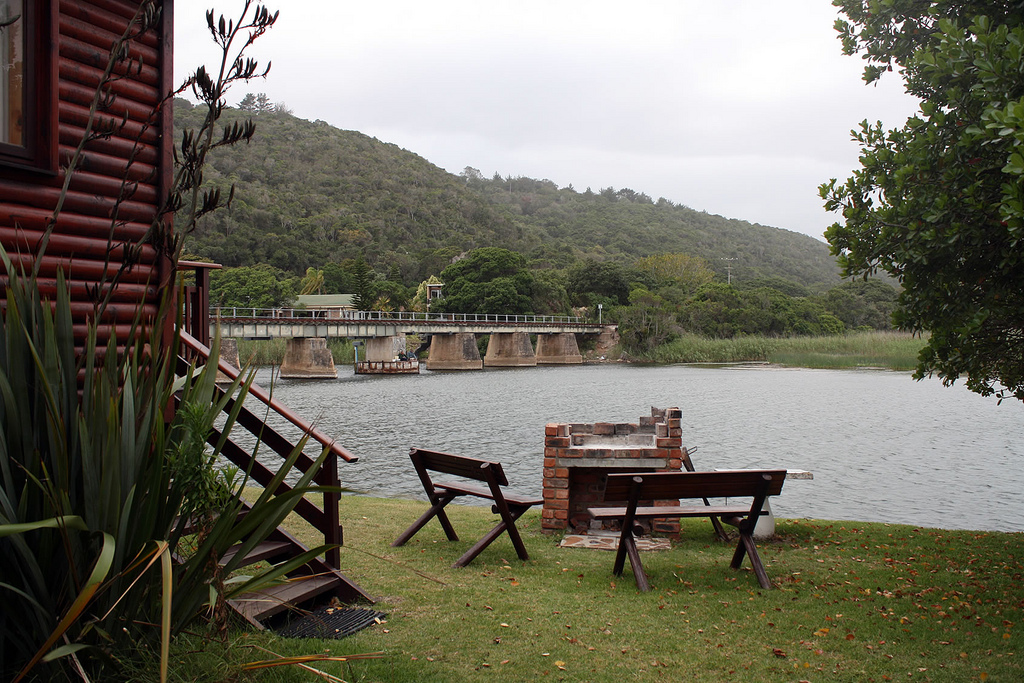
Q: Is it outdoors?
A: Yes, it is outdoors.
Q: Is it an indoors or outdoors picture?
A: It is outdoors.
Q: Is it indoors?
A: No, it is outdoors.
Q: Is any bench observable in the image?
A: Yes, there is a bench.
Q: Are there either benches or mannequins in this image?
A: Yes, there is a bench.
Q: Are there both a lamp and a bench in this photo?
A: No, there is a bench but no lamps.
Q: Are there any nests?
A: No, there are no nests.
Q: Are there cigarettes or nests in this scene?
A: No, there are no nests or cigarettes.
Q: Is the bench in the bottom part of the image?
A: Yes, the bench is in the bottom of the image.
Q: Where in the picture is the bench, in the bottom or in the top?
A: The bench is in the bottom of the image.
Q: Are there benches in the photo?
A: Yes, there is a bench.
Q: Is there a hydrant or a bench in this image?
A: Yes, there is a bench.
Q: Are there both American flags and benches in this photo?
A: No, there is a bench but no American flags.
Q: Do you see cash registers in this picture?
A: No, there are no cash registers.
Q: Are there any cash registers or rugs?
A: No, there are no cash registers or rugs.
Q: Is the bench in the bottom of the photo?
A: Yes, the bench is in the bottom of the image.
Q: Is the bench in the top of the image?
A: No, the bench is in the bottom of the image.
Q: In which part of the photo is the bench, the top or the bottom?
A: The bench is in the bottom of the image.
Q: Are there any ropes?
A: No, there are no ropes.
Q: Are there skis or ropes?
A: No, there are no ropes or skis.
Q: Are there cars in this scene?
A: No, there are no cars.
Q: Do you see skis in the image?
A: No, there are no skis.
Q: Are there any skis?
A: No, there are no skis.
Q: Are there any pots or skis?
A: No, there are no skis or pots.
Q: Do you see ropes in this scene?
A: No, there are no ropes.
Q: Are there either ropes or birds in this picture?
A: No, there are no ropes or birds.